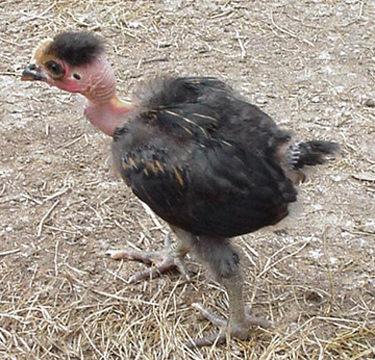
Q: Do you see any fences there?
A: No, there are no fences.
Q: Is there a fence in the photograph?
A: No, there are no fences.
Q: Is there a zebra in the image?
A: No, there are no zebras.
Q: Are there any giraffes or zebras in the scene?
A: No, there are no zebras or giraffes.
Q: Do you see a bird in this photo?
A: Yes, there is a bird.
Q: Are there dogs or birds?
A: Yes, there is a bird.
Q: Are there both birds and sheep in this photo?
A: No, there is a bird but no sheep.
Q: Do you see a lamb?
A: No, there are no lambs.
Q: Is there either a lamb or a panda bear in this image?
A: No, there are no lambs or pandas.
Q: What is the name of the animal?
A: The animal is a bird.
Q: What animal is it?
A: The animal is a bird.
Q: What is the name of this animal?
A: This is a bird.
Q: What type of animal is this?
A: This is a bird.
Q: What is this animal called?
A: This is a bird.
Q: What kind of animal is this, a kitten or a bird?
A: This is a bird.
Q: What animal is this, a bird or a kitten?
A: This is a bird.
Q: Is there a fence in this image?
A: No, there are no fences.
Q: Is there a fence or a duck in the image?
A: No, there are no fences or ducks.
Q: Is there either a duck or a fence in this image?
A: No, there are no fences or ducks.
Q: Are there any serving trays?
A: No, there are no serving trays.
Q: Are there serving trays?
A: No, there are no serving trays.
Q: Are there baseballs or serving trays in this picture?
A: No, there are no serving trays or baseballs.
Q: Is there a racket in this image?
A: No, there are no rackets.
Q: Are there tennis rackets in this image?
A: No, there are no tennis rackets.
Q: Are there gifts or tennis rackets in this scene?
A: No, there are no tennis rackets or gifts.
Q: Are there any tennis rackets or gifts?
A: No, there are no tennis rackets or gifts.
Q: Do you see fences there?
A: No, there are no fences.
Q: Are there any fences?
A: No, there are no fences.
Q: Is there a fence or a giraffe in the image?
A: No, there are no fences or giraffes.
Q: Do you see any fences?
A: No, there are no fences.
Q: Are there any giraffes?
A: No, there are no giraffes.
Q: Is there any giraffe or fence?
A: No, there are no giraffes or fences.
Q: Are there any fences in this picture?
A: No, there are no fences.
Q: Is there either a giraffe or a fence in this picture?
A: No, there are no fences or giraffes.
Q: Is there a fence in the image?
A: No, there are no fences.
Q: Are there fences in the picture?
A: No, there are no fences.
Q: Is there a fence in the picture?
A: No, there are no fences.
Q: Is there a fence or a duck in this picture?
A: No, there are no fences or ducks.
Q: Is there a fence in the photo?
A: No, there are no fences.